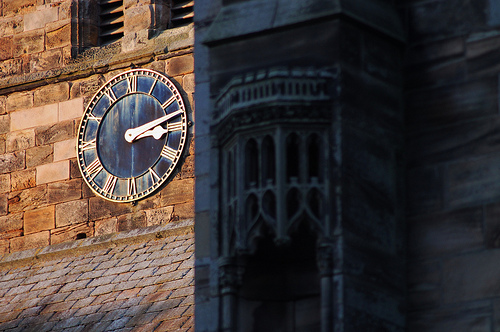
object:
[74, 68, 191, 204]
clock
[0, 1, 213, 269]
wall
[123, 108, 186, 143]
hands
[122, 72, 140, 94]
numerals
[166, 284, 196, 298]
shingles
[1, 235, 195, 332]
roof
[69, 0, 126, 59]
windows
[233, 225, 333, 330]
entrance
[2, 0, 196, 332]
building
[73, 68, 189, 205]
time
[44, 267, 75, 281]
bricks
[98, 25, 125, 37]
shutters